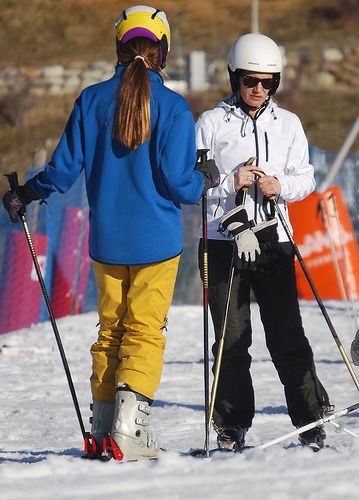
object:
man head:
[227, 33, 281, 107]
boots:
[100, 387, 168, 462]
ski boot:
[81, 400, 114, 460]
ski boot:
[298, 405, 335, 452]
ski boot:
[211, 419, 250, 451]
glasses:
[242, 75, 278, 89]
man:
[2, 5, 219, 465]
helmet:
[115, 5, 171, 69]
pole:
[252, 171, 359, 394]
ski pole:
[197, 149, 210, 458]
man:
[194, 33, 329, 455]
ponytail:
[88, 58, 154, 152]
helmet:
[227, 33, 282, 111]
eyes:
[244, 76, 259, 87]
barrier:
[0, 140, 359, 335]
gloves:
[250, 218, 290, 281]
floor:
[191, 50, 206, 92]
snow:
[0, 301, 359, 500]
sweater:
[30, 65, 204, 266]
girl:
[2, 5, 219, 462]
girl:
[193, 33, 330, 450]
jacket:
[29, 63, 204, 266]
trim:
[88, 247, 183, 264]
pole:
[3, 171, 85, 436]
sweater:
[195, 95, 316, 242]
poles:
[203, 157, 257, 450]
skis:
[190, 33, 359, 456]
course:
[0, 0, 359, 500]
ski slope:
[1, 301, 356, 497]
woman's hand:
[196, 159, 220, 196]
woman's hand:
[234, 165, 262, 192]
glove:
[217, 204, 264, 270]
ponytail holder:
[135, 55, 145, 62]